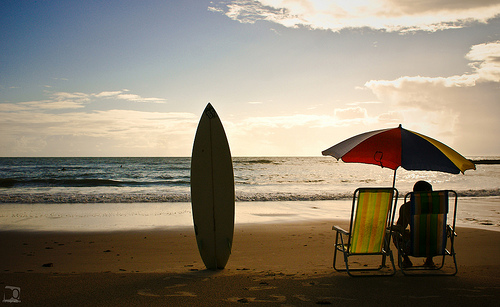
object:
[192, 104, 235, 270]
surfboard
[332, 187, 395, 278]
chair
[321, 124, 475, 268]
umbrella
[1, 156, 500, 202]
ocean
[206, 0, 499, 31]
clouds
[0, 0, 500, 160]
sky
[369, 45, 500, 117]
edge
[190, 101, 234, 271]
edge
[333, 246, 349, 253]
metal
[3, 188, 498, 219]
edge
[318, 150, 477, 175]
edge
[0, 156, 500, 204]
water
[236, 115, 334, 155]
sun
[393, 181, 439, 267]
man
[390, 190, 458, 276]
chair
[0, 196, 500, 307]
beach grounds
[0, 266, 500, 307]
print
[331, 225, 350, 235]
arm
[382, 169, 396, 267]
pole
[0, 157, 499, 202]
ocean waves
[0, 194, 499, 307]
shore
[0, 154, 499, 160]
line